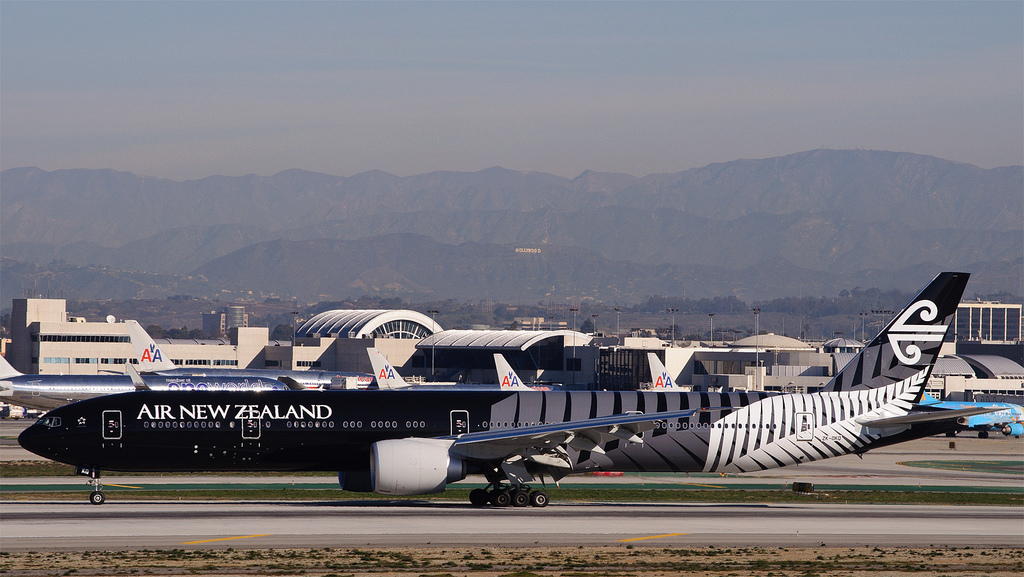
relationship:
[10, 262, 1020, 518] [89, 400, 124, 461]
plane has door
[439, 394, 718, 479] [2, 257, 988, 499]
wing of plane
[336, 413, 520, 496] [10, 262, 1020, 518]
turbine of plane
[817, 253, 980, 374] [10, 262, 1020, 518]
tail of plane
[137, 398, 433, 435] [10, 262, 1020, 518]
windows of plane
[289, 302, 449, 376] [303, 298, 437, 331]
building has roof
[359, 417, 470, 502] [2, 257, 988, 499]
engine on plane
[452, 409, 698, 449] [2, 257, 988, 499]
wing on plane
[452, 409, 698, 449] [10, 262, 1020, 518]
wing on plane